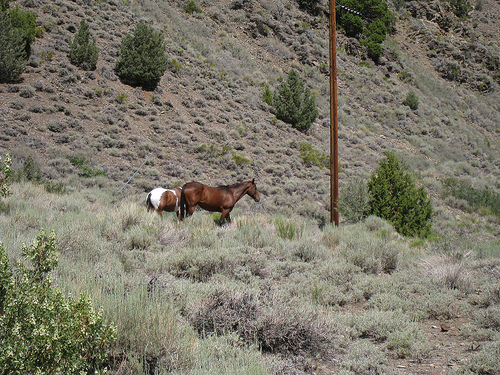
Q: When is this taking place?
A: Daytime.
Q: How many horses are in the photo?
A: Two.